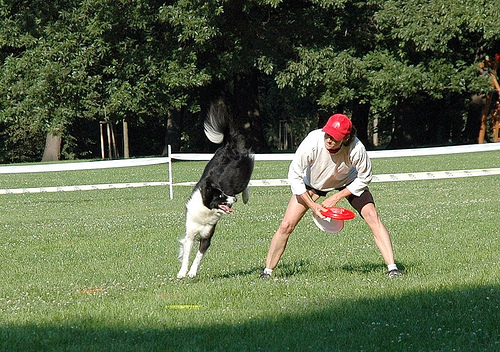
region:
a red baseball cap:
[323, 114, 353, 145]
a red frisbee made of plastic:
[323, 202, 355, 221]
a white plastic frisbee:
[312, 209, 346, 237]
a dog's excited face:
[204, 182, 236, 217]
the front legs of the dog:
[175, 233, 212, 280]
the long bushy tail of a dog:
[204, 103, 238, 148]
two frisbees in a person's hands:
[309, 202, 356, 234]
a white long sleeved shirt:
[287, 126, 373, 198]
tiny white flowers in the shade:
[317, 294, 497, 347]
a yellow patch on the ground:
[164, 299, 206, 309]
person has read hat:
[318, 109, 362, 153]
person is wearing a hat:
[303, 113, 363, 168]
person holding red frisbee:
[307, 181, 369, 253]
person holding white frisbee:
[290, 190, 341, 246]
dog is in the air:
[150, 115, 255, 252]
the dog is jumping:
[130, 117, 306, 272]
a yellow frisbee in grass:
[160, 280, 215, 321]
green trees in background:
[77, 22, 397, 103]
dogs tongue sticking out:
[192, 187, 248, 228]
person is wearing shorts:
[284, 175, 377, 230]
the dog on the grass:
[156, 103, 285, 285]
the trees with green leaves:
[0, 2, 499, 97]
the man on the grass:
[270, 110, 411, 286]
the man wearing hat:
[281, 106, 416, 288]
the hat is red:
[308, 111, 357, 144]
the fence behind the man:
[4, 147, 498, 195]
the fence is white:
[2, 143, 497, 198]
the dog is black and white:
[159, 103, 262, 289]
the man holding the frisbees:
[263, 103, 413, 285]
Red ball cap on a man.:
[321, 112, 354, 147]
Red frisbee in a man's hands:
[316, 206, 356, 221]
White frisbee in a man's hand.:
[311, 210, 344, 235]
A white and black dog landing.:
[176, 101, 255, 278]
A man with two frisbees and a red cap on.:
[260, 114, 405, 280]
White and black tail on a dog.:
[201, 104, 238, 149]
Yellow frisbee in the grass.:
[163, 302, 206, 308]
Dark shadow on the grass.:
[1, 289, 499, 351]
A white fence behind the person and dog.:
[1, 143, 499, 198]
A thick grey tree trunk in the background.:
[38, 111, 65, 162]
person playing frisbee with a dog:
[28, 16, 487, 330]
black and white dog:
[158, 94, 257, 282]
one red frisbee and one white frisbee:
[306, 198, 355, 235]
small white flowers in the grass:
[9, 207, 88, 311]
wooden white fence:
[11, 127, 483, 207]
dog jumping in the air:
[168, 92, 252, 282]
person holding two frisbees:
[256, 104, 396, 289]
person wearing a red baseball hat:
[302, 106, 365, 163]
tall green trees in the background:
[10, 16, 478, 141]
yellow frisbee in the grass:
[154, 294, 212, 321]